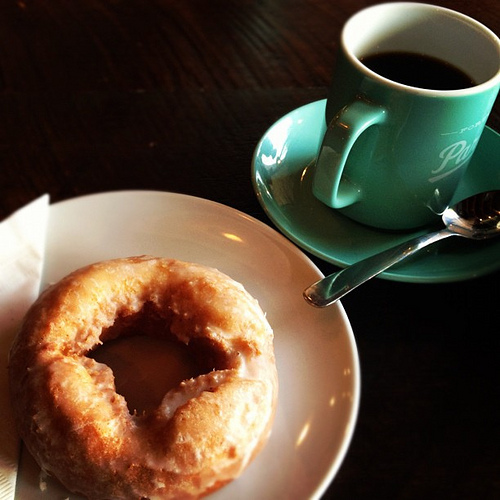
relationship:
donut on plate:
[16, 251, 298, 481] [5, 164, 383, 496]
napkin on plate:
[0, 195, 48, 498] [5, 164, 383, 496]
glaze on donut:
[157, 257, 288, 448] [5, 251, 281, 500]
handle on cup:
[310, 98, 387, 211] [302, 11, 483, 269]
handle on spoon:
[305, 215, 470, 341] [292, 173, 483, 304]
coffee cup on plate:
[310, 0, 500, 234] [239, 66, 483, 311]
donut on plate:
[5, 251, 281, 500] [5, 164, 383, 496]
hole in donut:
[67, 293, 236, 426] [7, 237, 332, 487]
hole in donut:
[97, 296, 213, 427] [5, 251, 281, 500]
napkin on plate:
[5, 169, 59, 496] [5, 164, 383, 496]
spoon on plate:
[297, 194, 484, 351] [239, 66, 483, 311]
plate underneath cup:
[0, 188, 366, 499] [311, 3, 483, 293]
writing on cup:
[431, 140, 467, 174] [298, 9, 484, 249]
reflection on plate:
[287, 376, 363, 460] [5, 164, 383, 496]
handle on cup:
[307, 83, 406, 241] [298, 9, 484, 249]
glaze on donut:
[208, 270, 279, 470] [5, 251, 281, 500]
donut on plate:
[5, 251, 281, 500] [243, 82, 500, 282]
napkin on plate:
[0, 195, 48, 498] [243, 82, 500, 282]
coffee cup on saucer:
[310, 0, 500, 234] [251, 90, 494, 283]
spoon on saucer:
[297, 194, 500, 310] [251, 90, 494, 283]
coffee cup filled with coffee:
[310, 0, 500, 234] [372, 47, 455, 89]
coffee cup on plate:
[310, 0, 500, 234] [251, 92, 496, 286]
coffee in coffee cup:
[354, 47, 479, 91] [310, 0, 500, 234]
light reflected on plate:
[288, 419, 315, 451] [243, 82, 500, 282]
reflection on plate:
[255, 117, 295, 202] [251, 92, 496, 286]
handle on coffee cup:
[310, 98, 387, 211] [310, 0, 500, 234]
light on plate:
[221, 229, 248, 245] [243, 82, 500, 282]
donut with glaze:
[5, 251, 281, 500] [221, 400, 259, 449]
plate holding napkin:
[243, 82, 500, 282] [0, 195, 48, 498]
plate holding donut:
[243, 82, 500, 282] [5, 251, 281, 500]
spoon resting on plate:
[297, 194, 500, 310] [251, 92, 496, 286]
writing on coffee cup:
[434, 135, 464, 179] [310, 5, 495, 235]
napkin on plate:
[0, 195, 48, 498] [47, 190, 439, 494]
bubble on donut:
[190, 370, 241, 418] [14, 260, 477, 480]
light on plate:
[262, 113, 292, 155] [243, 82, 500, 282]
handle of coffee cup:
[310, 98, 387, 211] [310, 0, 500, 234]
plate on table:
[11, 191, 289, 499] [38, 28, 268, 181]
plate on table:
[243, 82, 500, 282] [40, 31, 201, 161]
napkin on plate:
[0, 195, 48, 498] [58, 189, 343, 499]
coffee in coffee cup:
[360, 36, 480, 93] [310, 0, 500, 234]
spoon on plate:
[297, 194, 500, 310] [264, 82, 483, 293]